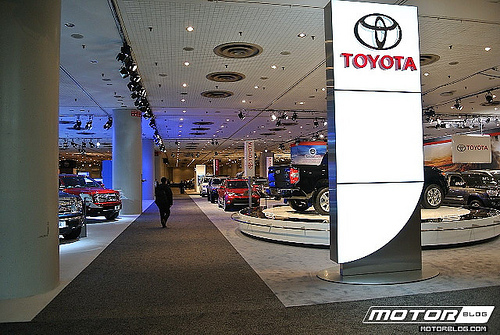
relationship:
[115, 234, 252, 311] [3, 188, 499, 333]
carpet on floor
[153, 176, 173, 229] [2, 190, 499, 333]
man walking on carpet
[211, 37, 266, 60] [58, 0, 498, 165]
vent on ceiling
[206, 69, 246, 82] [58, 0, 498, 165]
vent on ceiling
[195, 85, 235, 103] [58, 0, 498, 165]
vent on ceiling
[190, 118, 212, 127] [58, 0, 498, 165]
vent on ceiling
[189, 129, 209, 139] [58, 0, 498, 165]
vent on ceiling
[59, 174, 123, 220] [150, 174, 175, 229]
suv beside man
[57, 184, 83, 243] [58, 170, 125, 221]
truck in front of truck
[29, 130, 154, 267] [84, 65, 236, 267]
truck next to pillar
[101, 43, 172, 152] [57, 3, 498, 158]
lights hanging from roof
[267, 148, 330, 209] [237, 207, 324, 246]
truckbed on platform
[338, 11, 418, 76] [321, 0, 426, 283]
logo on sign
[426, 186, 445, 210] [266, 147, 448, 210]
front tire of truck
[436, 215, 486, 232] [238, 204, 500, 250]
rail on pedestal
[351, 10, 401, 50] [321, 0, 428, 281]
drawing made on board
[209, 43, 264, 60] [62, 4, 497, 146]
air vent on ceiling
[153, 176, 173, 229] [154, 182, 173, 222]
man wearing suit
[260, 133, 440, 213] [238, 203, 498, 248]
truck parked on pedestal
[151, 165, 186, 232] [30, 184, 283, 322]
man walking on carpet